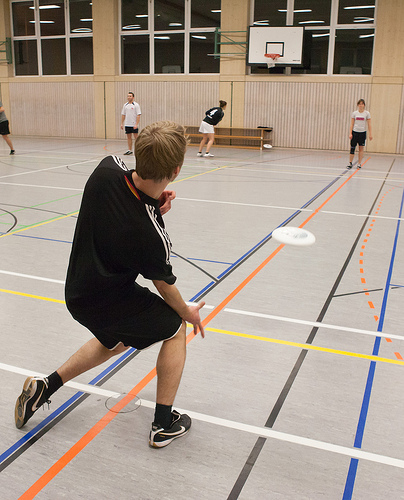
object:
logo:
[158, 425, 187, 437]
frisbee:
[271, 224, 317, 247]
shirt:
[67, 154, 175, 316]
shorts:
[63, 283, 184, 350]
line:
[18, 154, 374, 500]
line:
[229, 156, 394, 499]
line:
[353, 176, 404, 364]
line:
[4, 161, 353, 455]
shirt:
[203, 107, 224, 124]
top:
[351, 109, 371, 133]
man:
[120, 91, 143, 156]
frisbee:
[262, 143, 273, 149]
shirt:
[351, 109, 372, 132]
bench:
[183, 125, 272, 151]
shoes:
[12, 374, 52, 432]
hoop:
[263, 52, 280, 69]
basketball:
[247, 24, 302, 68]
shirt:
[121, 101, 141, 128]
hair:
[135, 121, 189, 181]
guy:
[13, 120, 193, 451]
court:
[1, 135, 398, 492]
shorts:
[350, 130, 366, 146]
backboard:
[246, 24, 305, 68]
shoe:
[148, 409, 191, 448]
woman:
[350, 101, 374, 168]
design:
[209, 109, 218, 116]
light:
[135, 13, 148, 18]